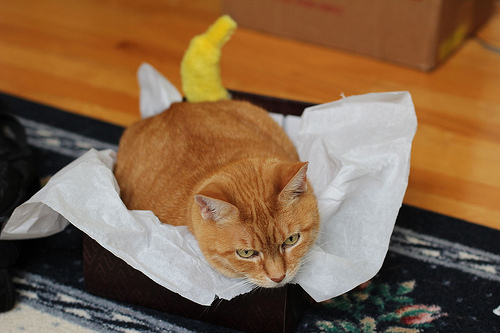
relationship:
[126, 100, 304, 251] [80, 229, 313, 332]
cat in box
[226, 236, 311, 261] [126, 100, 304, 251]
eyes of cat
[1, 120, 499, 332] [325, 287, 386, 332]
rug has flowers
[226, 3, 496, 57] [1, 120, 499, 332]
box behind rug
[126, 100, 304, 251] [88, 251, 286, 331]
cat on box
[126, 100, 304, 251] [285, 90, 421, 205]
cat on tissue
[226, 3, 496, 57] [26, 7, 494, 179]
box on floor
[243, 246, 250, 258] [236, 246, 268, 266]
dot in eye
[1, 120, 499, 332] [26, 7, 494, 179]
rug on floor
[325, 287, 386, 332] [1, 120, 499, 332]
flowers on rug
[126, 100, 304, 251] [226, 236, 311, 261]
cat has eyes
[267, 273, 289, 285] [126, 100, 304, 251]
nose of cat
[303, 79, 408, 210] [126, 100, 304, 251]
paper beneath cat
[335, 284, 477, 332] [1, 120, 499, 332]
pattern on rug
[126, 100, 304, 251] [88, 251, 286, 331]
cat in box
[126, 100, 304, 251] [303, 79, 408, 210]
cat on paper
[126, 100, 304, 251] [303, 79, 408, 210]
cat in paper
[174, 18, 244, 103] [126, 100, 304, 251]
toy of cat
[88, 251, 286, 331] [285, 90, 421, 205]
box of tissue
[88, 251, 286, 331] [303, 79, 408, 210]
box of paper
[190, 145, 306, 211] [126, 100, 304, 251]
ears of cat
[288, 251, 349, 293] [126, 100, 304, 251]
whiskers of cat